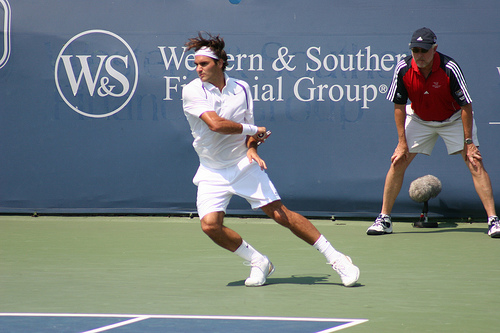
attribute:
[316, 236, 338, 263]
socks — white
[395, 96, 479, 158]
shorts — grey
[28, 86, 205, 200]
wall — blue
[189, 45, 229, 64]
band — white, thick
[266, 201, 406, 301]
feet — players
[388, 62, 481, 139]
tshirt — red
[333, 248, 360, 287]
shoes — white, tennis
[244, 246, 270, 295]
shoes — white, tennis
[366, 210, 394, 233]
shoes — white, tennis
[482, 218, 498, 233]
shoes — white, tennis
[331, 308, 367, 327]
edge — white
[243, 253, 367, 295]
sneakers — new, pair, white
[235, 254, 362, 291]
shoes — pure white, tennis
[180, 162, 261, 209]
shorts — white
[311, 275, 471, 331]
floor — green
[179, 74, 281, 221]
white clothes — tennis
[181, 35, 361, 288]
player — tennis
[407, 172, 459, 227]
thing — grey, fuzzy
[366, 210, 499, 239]
shoes — white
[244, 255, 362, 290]
shoes — white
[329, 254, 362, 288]
shoes — white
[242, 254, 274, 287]
shoes — white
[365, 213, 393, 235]
shoes — white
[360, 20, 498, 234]
ball boy — ready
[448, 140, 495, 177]
hand — mans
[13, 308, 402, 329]
lines — white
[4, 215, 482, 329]
tennis court — blue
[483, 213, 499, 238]
shoe — white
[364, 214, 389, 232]
shoe — white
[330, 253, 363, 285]
shoe — white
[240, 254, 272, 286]
shoe — white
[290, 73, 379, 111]
word — white, group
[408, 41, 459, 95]
shirt — red, white, black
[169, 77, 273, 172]
polo — white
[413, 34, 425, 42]
logo — small, white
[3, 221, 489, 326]
court — blue, green, tennis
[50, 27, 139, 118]
circle — white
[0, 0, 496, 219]
wall — back, blue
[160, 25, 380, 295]
man — crazy, brown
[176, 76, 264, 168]
t shirt — white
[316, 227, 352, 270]
sock — tall, white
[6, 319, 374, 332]
court — blue